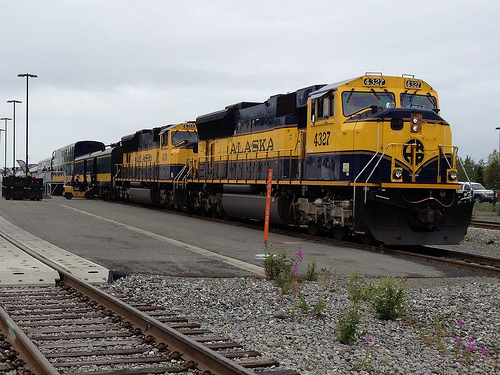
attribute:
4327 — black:
[313, 132, 331, 147]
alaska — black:
[230, 138, 274, 154]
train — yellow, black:
[0, 72, 476, 246]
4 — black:
[313, 133, 318, 147]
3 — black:
[318, 131, 323, 147]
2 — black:
[322, 132, 327, 145]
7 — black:
[326, 131, 331, 145]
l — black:
[235, 141, 245, 153]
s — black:
[251, 139, 260, 152]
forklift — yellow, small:
[62, 165, 98, 200]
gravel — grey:
[0, 227, 500, 374]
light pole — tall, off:
[18, 73, 37, 176]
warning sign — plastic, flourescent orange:
[264, 169, 274, 243]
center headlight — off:
[412, 124, 420, 132]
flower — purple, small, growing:
[482, 346, 490, 357]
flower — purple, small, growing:
[456, 315, 465, 327]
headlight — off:
[394, 170, 402, 178]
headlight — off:
[449, 170, 458, 180]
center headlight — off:
[413, 115, 420, 124]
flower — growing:
[363, 335, 371, 342]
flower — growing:
[292, 263, 300, 273]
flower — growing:
[294, 246, 304, 261]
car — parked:
[459, 182, 496, 203]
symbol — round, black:
[402, 139, 424, 166]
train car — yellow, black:
[196, 84, 319, 186]